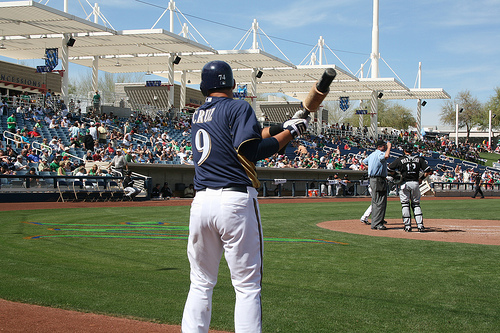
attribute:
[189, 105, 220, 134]
lettering — white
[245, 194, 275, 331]
strip — blue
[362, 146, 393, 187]
shirt — light blue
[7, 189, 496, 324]
grass — green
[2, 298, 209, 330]
dirt — brown